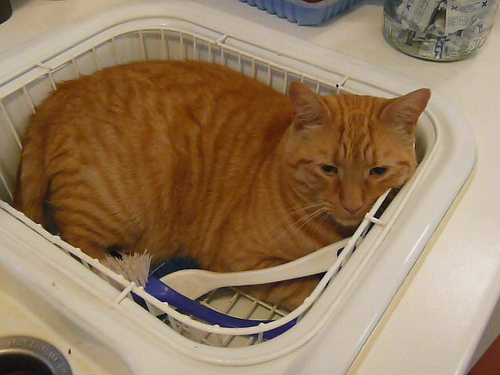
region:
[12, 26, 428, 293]
An orange cat lies in the sink.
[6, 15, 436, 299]
An orange striped cat lies in the dish rack.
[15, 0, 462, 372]
The kitchen counter is white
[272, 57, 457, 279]
An orange cat looks sleepy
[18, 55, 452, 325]
An orange cat rests near one white dish scrubber.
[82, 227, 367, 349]
There is one blue and one white dish scrubber.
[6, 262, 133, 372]
The sink is either dirty or old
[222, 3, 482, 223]
An orange cat rests next to a blueish canister.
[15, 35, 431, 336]
An orange striped cat lies in a dish rack.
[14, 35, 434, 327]
An orange striped cat rests in the sink.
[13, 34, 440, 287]
Orange tabby cat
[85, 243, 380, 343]
Blue and white bristle brushes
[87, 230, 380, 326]
Two brushes sitting in the sink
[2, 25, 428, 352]
Wire rack sitting in the sink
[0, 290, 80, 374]
Drain for the sink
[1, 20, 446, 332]
Orange cat sitting in the sink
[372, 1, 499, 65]
Jar of packaged wipes sitting on the counter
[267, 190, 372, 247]
Cat's wiskers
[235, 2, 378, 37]
Blue container sitting on the counter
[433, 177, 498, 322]
White counter top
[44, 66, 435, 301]
cat laying in dish drainer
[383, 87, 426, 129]
left ear of cat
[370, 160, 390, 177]
left eye of cat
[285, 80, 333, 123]
right ear of cat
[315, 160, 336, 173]
right eye of cat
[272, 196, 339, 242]
right whiskers of cat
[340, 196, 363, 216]
pink nose of cat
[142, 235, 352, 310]
white scrub brush with blue bristles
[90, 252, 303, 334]
blue scrub brush with white bristles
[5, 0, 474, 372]
right side of sink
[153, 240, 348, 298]
this is a spoon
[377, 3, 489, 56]
this is a jar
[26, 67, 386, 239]
this is a cat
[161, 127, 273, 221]
the fur is brown in color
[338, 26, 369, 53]
the table is white in color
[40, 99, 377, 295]
the cat is lying down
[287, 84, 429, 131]
the ears are raised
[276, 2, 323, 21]
this is a tray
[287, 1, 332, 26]
the tray is blue in color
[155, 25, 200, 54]
this object is made of metal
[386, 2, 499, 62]
A can filled with something on a counter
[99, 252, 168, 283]
The white bristles of a brush inside the dish tray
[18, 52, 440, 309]
A cat sitting in a white dish tray in the sink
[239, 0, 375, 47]
The edge of a blue object on the kitchen counter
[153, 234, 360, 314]
A white brush with black bristles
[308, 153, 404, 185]
The cat's eyes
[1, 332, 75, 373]
The sink drain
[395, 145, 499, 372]
The White edge of the sink counter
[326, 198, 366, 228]
The cat's little mouth